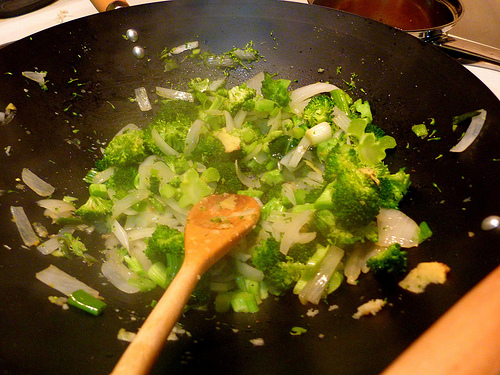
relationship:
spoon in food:
[104, 193, 264, 373] [70, 64, 431, 321]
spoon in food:
[104, 193, 264, 373] [137, 98, 391, 274]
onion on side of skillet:
[444, 111, 484, 157] [4, 3, 484, 373]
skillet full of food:
[4, 3, 484, 373] [70, 64, 431, 321]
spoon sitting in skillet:
[104, 193, 264, 373] [4, 3, 484, 373]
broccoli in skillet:
[303, 167, 389, 248] [4, 3, 484, 373]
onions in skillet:
[275, 77, 345, 178] [4, 3, 484, 373]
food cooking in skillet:
[70, 64, 431, 321] [4, 3, 484, 373]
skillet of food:
[4, 3, 484, 373] [70, 64, 431, 321]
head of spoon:
[179, 190, 265, 273] [104, 193, 264, 373]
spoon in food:
[104, 193, 264, 373] [76, 76, 413, 328]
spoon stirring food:
[104, 193, 264, 373] [70, 64, 431, 321]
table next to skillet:
[353, 242, 498, 372] [4, 3, 484, 373]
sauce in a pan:
[328, 7, 437, 47] [350, 0, 468, 54]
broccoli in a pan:
[88, 82, 402, 320] [6, 9, 498, 367]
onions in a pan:
[132, 71, 368, 120] [6, 9, 498, 367]